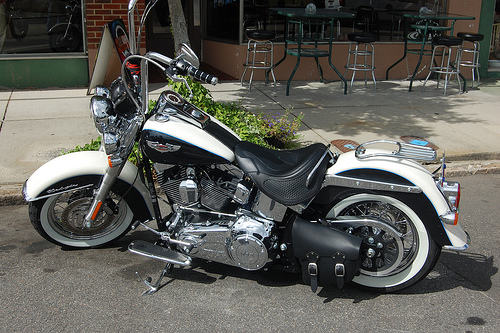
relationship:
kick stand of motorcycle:
[135, 259, 171, 298] [25, 2, 471, 306]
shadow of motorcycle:
[58, 227, 500, 305] [25, 2, 471, 306]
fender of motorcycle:
[450, 222, 471, 251] [25, 2, 471, 306]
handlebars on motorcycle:
[128, 2, 219, 115] [25, 2, 471, 306]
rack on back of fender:
[357, 136, 438, 168] [450, 222, 471, 251]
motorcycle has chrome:
[25, 2, 471, 306] [127, 160, 270, 302]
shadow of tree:
[215, 76, 482, 145] [165, 2, 194, 89]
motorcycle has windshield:
[25, 2, 471, 306] [127, 2, 163, 111]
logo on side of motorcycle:
[147, 138, 183, 154] [25, 2, 471, 306]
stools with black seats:
[424, 33, 487, 93] [433, 32, 485, 46]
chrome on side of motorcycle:
[127, 160, 270, 302] [25, 2, 471, 306]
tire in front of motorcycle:
[27, 177, 139, 250] [25, 2, 471, 306]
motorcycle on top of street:
[25, 2, 471, 306] [1, 171, 500, 332]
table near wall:
[383, 7, 476, 91] [202, 0, 500, 83]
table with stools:
[265, 6, 355, 100] [239, 31, 381, 94]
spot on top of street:
[24, 237, 55, 259] [1, 171, 500, 332]